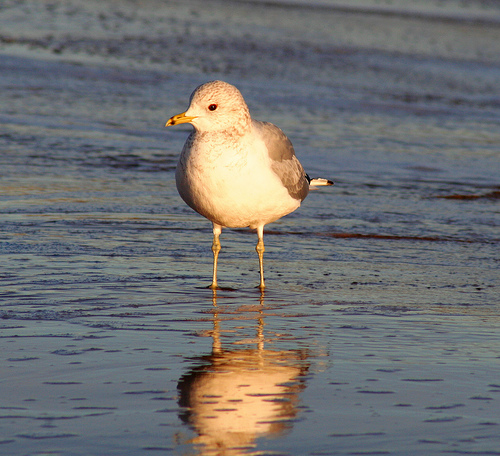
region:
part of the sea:
[375, 395, 385, 409]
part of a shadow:
[234, 390, 249, 418]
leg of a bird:
[253, 278, 273, 290]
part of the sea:
[376, 288, 392, 313]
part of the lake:
[99, 265, 124, 299]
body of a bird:
[272, 169, 280, 181]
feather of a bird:
[272, 157, 279, 173]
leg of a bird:
[213, 251, 216, 271]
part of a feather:
[319, 173, 321, 185]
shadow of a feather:
[261, 398, 269, 405]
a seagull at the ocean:
[135, 60, 364, 300]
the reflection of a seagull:
[175, 287, 315, 452]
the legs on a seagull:
[196, 223, 279, 302]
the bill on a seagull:
[161, 105, 199, 134]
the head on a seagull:
[161, 80, 257, 143]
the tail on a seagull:
[298, 165, 340, 197]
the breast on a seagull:
[186, 150, 278, 204]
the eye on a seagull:
[205, 102, 219, 112]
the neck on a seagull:
[194, 120, 256, 140]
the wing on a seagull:
[249, 125, 311, 210]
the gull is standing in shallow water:
[153, 72, 344, 306]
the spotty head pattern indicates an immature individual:
[153, 75, 260, 157]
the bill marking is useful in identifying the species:
[161, 112, 180, 129]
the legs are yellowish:
[194, 228, 281, 299]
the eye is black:
[206, 102, 218, 112]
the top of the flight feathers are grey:
[262, 132, 313, 206]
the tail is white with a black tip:
[305, 172, 338, 197]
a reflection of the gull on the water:
[161, 293, 298, 454]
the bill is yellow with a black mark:
[159, 108, 197, 129]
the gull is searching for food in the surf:
[156, 74, 339, 317]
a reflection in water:
[127, 268, 343, 453]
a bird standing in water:
[97, 62, 463, 439]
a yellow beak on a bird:
[161, 75, 346, 325]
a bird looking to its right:
[140, 80, 332, 295]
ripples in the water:
[25, 285, 432, 370]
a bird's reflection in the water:
[115, 50, 352, 450]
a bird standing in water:
[151, 80, 341, 295]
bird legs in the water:
[160, 235, 325, 320]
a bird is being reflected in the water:
[79, 80, 379, 450]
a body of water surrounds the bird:
[36, 15, 415, 352]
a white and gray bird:
[163, 79, 335, 289]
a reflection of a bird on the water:
[176, 289, 310, 454]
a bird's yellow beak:
[163, 111, 192, 127]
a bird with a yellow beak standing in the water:
[165, 80, 336, 292]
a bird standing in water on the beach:
[1, 36, 498, 316]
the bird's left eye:
[207, 102, 218, 113]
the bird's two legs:
[210, 223, 270, 291]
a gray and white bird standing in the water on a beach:
[163, 77, 333, 292]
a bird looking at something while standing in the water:
[0, 77, 498, 319]